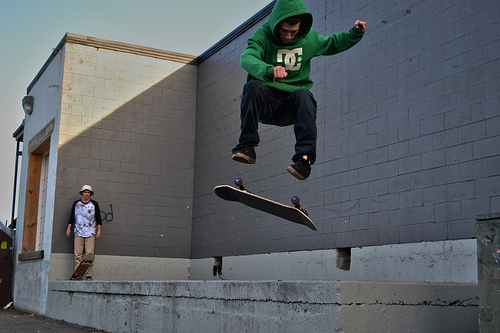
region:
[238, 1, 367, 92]
a green DC sweatshirt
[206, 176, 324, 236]
a skateboard in the air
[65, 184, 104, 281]
a man standing with a skateboard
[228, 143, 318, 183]
a man with black shoes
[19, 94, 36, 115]
a light fixture on the wall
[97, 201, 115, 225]
graffiti on the wall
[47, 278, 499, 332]
a worn concrete floor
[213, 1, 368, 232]
a man jumping with a skateboard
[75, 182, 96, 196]
a white hat in the daytime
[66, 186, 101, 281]
a man with a grey and black shirt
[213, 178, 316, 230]
skateboard upside down in the air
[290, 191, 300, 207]
front purple wheel on skateboard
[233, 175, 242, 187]
rear purple wheel on skateboard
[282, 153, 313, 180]
black skateboarding shoe on left foot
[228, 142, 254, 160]
black skateboarding shoe on right foot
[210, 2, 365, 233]
skateboarder doing a trick in air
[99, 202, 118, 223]
grafitti on the wall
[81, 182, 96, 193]
white hat on person's head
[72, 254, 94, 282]
skateboard on the ground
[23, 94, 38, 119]
light fixture on the wall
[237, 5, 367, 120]
the hoodie is green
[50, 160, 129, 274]
a man standing by the wall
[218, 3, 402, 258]
The skateboarding is doing a trick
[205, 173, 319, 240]
The skateboard is black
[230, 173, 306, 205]
The skateboard has purple wheels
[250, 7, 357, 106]
The man is wearing a green sweater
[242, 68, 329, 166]
The man is wearing black pants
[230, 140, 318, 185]
The man is wearing black shoes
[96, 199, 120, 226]
Graffitti is on the wall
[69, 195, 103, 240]
The man is wearing a white and black shirt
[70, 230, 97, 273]
The man is wearing tan pants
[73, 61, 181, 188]
The wall is made of bricks